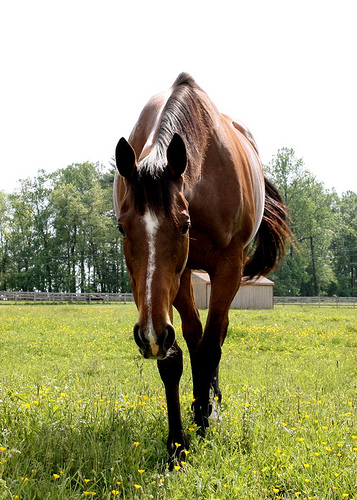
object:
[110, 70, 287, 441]
horse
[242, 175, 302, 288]
tail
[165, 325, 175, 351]
nostrils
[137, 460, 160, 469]
flower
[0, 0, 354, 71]
clouds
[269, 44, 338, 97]
white clouds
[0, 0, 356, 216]
sky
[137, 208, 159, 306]
white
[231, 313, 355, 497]
grass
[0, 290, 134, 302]
fencing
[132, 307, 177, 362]
nose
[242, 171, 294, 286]
hair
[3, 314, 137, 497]
field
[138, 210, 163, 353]
stripe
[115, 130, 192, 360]
head